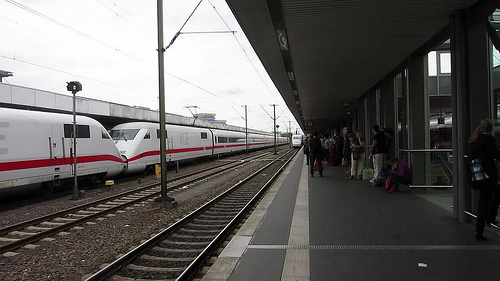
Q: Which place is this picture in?
A: It is at the train station.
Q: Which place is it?
A: It is a train station.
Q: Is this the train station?
A: Yes, it is the train station.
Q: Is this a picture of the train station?
A: Yes, it is showing the train station.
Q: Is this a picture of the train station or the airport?
A: It is showing the train station.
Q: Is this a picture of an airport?
A: No, the picture is showing a train station.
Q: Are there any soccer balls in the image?
A: No, there are no soccer balls.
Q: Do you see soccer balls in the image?
A: No, there are no soccer balls.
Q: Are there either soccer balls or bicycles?
A: No, there are no soccer balls or bicycles.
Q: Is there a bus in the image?
A: No, there are no buses.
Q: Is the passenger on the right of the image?
A: Yes, the passenger is on the right of the image.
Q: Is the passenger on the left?
A: No, the passenger is on the right of the image.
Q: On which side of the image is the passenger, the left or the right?
A: The passenger is on the right of the image.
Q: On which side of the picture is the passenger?
A: The passenger is on the right of the image.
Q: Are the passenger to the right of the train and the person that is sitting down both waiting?
A: Yes, both the passenger and the person are waiting.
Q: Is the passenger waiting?
A: Yes, the passenger is waiting.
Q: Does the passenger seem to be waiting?
A: Yes, the passenger is waiting.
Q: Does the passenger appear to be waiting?
A: Yes, the passenger is waiting.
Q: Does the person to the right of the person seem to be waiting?
A: Yes, the passenger is waiting.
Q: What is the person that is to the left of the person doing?
A: The passenger is waiting.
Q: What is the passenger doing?
A: The passenger is waiting.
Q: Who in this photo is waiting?
A: The passenger is waiting.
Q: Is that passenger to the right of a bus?
A: No, the passenger is to the right of the train.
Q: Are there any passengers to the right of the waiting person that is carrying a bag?
A: Yes, there is a passenger to the right of the person.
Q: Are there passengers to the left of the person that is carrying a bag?
A: No, the passenger is to the right of the person.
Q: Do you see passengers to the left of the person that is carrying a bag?
A: No, the passenger is to the right of the person.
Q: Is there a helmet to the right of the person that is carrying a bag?
A: No, there is a passenger to the right of the person.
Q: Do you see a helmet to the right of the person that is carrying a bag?
A: No, there is a passenger to the right of the person.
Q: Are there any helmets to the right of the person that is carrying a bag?
A: No, there is a passenger to the right of the person.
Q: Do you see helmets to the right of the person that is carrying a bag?
A: No, there is a passenger to the right of the person.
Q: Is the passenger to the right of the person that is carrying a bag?
A: Yes, the passenger is to the right of the person.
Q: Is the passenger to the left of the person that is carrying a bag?
A: No, the passenger is to the right of the person.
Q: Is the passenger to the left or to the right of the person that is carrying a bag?
A: The passenger is to the right of the person.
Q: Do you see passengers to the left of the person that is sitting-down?
A: Yes, there is a passenger to the left of the person.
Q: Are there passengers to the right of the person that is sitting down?
A: No, the passenger is to the left of the person.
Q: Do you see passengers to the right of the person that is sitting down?
A: No, the passenger is to the left of the person.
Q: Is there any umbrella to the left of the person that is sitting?
A: No, there is a passenger to the left of the person.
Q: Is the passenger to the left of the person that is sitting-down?
A: Yes, the passenger is to the left of the person.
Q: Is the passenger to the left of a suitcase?
A: No, the passenger is to the left of the person.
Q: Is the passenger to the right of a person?
A: No, the passenger is to the left of a person.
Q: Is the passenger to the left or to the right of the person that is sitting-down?
A: The passenger is to the left of the person.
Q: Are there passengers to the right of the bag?
A: Yes, there is a passenger to the right of the bag.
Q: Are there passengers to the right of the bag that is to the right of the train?
A: Yes, there is a passenger to the right of the bag.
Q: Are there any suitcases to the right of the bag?
A: No, there is a passenger to the right of the bag.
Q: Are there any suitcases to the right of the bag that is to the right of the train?
A: No, there is a passenger to the right of the bag.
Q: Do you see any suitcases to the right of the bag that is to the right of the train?
A: No, there is a passenger to the right of the bag.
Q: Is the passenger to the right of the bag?
A: Yes, the passenger is to the right of the bag.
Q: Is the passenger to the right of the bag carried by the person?
A: Yes, the passenger is to the right of the bag.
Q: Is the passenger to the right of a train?
A: Yes, the passenger is to the right of a train.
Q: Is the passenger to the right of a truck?
A: No, the passenger is to the right of a train.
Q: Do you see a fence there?
A: No, there are no fences.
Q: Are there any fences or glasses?
A: No, there are no fences or glasses.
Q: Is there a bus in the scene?
A: No, there are no buses.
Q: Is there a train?
A: Yes, there is a train.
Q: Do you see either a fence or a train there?
A: Yes, there is a train.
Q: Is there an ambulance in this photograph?
A: No, there are no ambulances.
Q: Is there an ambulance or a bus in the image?
A: No, there are no ambulances or buses.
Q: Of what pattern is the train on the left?
A: The train is striped.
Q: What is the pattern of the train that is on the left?
A: The train is striped.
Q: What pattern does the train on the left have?
A: The train has striped pattern.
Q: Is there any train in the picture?
A: Yes, there is a train.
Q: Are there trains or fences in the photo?
A: Yes, there is a train.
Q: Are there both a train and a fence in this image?
A: No, there is a train but no fences.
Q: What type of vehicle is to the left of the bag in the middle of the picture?
A: The vehicle is a train.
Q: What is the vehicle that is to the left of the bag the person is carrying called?
A: The vehicle is a train.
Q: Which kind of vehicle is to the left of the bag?
A: The vehicle is a train.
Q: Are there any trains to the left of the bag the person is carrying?
A: Yes, there is a train to the left of the bag.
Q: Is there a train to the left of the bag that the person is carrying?
A: Yes, there is a train to the left of the bag.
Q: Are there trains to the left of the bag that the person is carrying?
A: Yes, there is a train to the left of the bag.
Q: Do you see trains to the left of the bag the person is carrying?
A: Yes, there is a train to the left of the bag.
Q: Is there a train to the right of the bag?
A: No, the train is to the left of the bag.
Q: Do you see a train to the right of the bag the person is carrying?
A: No, the train is to the left of the bag.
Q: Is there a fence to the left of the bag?
A: No, there is a train to the left of the bag.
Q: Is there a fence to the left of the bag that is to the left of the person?
A: No, there is a train to the left of the bag.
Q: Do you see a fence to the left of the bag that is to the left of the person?
A: No, there is a train to the left of the bag.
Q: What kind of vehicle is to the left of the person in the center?
A: The vehicle is a train.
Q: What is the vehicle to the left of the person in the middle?
A: The vehicle is a train.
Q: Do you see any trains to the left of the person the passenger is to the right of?
A: Yes, there is a train to the left of the person.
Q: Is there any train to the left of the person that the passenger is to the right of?
A: Yes, there is a train to the left of the person.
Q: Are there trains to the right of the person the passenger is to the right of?
A: No, the train is to the left of the person.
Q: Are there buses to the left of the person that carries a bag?
A: No, there is a train to the left of the person.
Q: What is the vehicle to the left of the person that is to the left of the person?
A: The vehicle is a train.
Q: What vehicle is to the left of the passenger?
A: The vehicle is a train.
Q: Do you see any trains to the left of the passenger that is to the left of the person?
A: Yes, there is a train to the left of the passenger.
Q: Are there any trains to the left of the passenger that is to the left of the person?
A: Yes, there is a train to the left of the passenger.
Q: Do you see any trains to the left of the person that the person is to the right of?
A: Yes, there is a train to the left of the passenger.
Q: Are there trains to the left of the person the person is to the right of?
A: Yes, there is a train to the left of the passenger.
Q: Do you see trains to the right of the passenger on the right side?
A: No, the train is to the left of the passenger.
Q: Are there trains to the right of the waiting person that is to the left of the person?
A: No, the train is to the left of the passenger.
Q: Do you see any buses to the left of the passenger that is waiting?
A: No, there is a train to the left of the passenger.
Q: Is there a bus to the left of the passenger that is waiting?
A: No, there is a train to the left of the passenger.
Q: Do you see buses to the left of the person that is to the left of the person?
A: No, there is a train to the left of the passenger.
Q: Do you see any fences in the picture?
A: No, there are no fences.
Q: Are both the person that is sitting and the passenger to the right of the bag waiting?
A: Yes, both the person and the passenger are waiting.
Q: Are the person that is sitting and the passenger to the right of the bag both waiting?
A: Yes, both the person and the passenger are waiting.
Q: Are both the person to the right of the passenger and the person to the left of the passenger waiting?
A: Yes, both the person and the person are waiting.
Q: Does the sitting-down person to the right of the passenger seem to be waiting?
A: Yes, the person is waiting.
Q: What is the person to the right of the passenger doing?
A: The person is waiting.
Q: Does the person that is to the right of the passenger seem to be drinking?
A: No, the person is waiting.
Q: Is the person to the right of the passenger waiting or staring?
A: The person is waiting.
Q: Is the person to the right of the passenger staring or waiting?
A: The person is waiting.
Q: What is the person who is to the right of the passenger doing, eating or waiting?
A: The person is waiting.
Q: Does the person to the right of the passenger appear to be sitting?
A: Yes, the person is sitting.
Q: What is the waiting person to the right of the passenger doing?
A: The person is sitting.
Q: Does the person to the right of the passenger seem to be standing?
A: No, the person is sitting.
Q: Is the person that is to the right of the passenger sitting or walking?
A: The person is sitting.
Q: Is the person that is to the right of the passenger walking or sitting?
A: The person is sitting.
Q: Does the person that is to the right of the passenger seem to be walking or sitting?
A: The person is sitting.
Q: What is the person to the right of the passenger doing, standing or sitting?
A: The person is sitting.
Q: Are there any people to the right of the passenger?
A: Yes, there is a person to the right of the passenger.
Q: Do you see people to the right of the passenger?
A: Yes, there is a person to the right of the passenger.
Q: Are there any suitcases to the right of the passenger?
A: No, there is a person to the right of the passenger.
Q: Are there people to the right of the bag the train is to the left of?
A: Yes, there is a person to the right of the bag.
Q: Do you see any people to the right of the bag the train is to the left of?
A: Yes, there is a person to the right of the bag.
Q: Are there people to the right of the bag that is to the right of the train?
A: Yes, there is a person to the right of the bag.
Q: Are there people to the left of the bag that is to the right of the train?
A: No, the person is to the right of the bag.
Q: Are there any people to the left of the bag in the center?
A: No, the person is to the right of the bag.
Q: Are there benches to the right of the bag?
A: No, there is a person to the right of the bag.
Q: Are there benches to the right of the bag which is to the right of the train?
A: No, there is a person to the right of the bag.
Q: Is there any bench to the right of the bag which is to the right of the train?
A: No, there is a person to the right of the bag.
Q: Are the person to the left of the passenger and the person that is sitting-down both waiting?
A: Yes, both the person and the person are waiting.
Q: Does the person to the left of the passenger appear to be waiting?
A: Yes, the person is waiting.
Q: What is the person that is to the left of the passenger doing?
A: The person is waiting.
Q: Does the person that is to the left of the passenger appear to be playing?
A: No, the person is waiting.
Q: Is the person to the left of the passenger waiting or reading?
A: The person is waiting.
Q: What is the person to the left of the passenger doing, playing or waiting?
A: The person is waiting.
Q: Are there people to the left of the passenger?
A: Yes, there is a person to the left of the passenger.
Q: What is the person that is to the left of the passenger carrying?
A: The person is carrying a bag.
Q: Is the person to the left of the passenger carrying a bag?
A: Yes, the person is carrying a bag.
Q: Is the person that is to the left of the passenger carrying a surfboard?
A: No, the person is carrying a bag.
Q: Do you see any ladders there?
A: No, there are no ladders.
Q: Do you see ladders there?
A: No, there are no ladders.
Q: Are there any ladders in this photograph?
A: No, there are no ladders.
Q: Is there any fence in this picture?
A: No, there are no fences.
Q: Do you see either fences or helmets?
A: No, there are no fences or helmets.